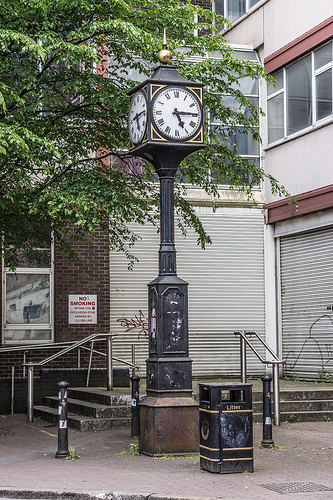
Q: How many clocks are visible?
A: 2.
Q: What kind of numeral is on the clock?
A: Roman.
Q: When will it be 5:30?
A: 15 minutes.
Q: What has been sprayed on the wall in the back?
A: Graffiti.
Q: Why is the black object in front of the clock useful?
A: Throw away trash.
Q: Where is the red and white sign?
A: Back wall.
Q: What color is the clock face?
A: White.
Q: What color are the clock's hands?
A: Black.